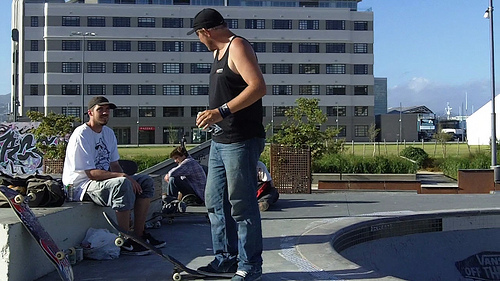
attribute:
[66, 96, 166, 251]
man — sitting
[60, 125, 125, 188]
shirt — white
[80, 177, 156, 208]
shorts — jean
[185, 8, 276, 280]
man — standing, forefront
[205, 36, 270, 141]
shirt — black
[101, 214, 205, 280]
skateboard — slanted, black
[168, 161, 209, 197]
shirt — plaid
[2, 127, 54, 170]
graffiti — black, purple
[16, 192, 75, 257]
wheels — white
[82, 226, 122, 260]
bag — white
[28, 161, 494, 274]
concrete — grey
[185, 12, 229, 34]
hat — black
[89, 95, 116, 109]
hat — black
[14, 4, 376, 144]
building — large, tall, grey, white, background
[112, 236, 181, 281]
wheels — white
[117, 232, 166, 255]
shoes — nike, black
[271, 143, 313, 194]
cage — brown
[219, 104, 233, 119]
band — black